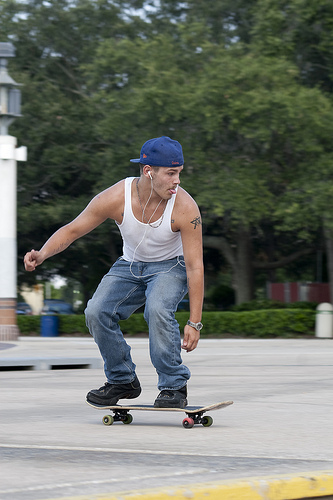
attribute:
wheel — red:
[180, 417, 192, 427]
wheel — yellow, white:
[104, 415, 111, 424]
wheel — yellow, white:
[181, 418, 193, 427]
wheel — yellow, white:
[202, 415, 210, 425]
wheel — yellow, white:
[120, 412, 130, 422]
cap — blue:
[131, 141, 200, 164]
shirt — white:
[113, 176, 183, 263]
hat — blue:
[127, 135, 186, 168]